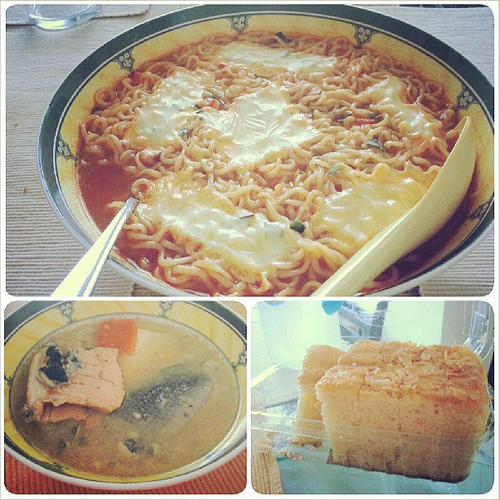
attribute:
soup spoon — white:
[308, 114, 480, 296]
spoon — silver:
[65, 94, 210, 293]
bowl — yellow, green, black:
[39, 1, 494, 293]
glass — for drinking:
[22, 3, 102, 33]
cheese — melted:
[221, 74, 326, 165]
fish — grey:
[107, 361, 223, 464]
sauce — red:
[76, 160, 150, 221]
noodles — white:
[270, 179, 320, 219]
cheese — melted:
[205, 116, 333, 200]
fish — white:
[26, 342, 127, 426]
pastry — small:
[289, 329, 495, 486]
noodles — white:
[83, 33, 458, 297]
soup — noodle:
[153, 79, 469, 278]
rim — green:
[37, 25, 126, 237]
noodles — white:
[152, 72, 377, 259]